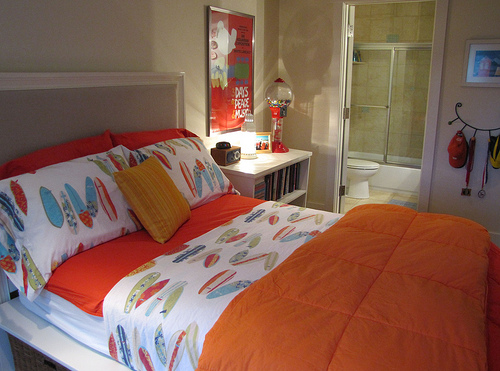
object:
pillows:
[112, 155, 191, 244]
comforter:
[102, 200, 500, 370]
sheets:
[101, 199, 345, 371]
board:
[0, 71, 185, 166]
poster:
[206, 4, 255, 136]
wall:
[0, 0, 207, 140]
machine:
[265, 77, 294, 153]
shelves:
[254, 152, 312, 207]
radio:
[216, 141, 232, 149]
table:
[218, 147, 313, 208]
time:
[233, 151, 240, 161]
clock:
[211, 146, 243, 166]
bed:
[0, 72, 487, 369]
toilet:
[345, 158, 380, 199]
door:
[345, 45, 430, 168]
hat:
[447, 130, 468, 168]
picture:
[459, 38, 500, 87]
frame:
[460, 38, 500, 88]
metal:
[460, 188, 471, 196]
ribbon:
[465, 136, 476, 186]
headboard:
[0, 68, 185, 163]